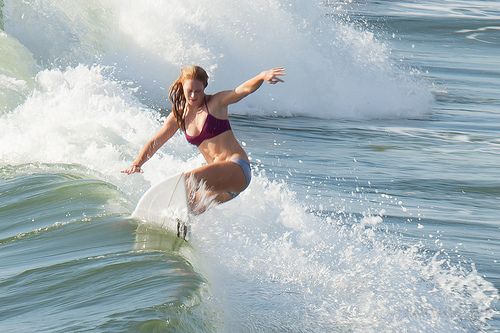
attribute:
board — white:
[128, 172, 194, 248]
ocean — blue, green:
[0, 2, 497, 330]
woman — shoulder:
[121, 64, 286, 214]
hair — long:
[167, 64, 209, 131]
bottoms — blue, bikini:
[228, 160, 253, 202]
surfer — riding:
[150, 48, 262, 236]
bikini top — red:
[181, 95, 230, 147]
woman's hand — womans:
[114, 156, 147, 184]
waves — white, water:
[159, 213, 474, 331]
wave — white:
[15, 63, 482, 331]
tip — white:
[159, 172, 189, 209]